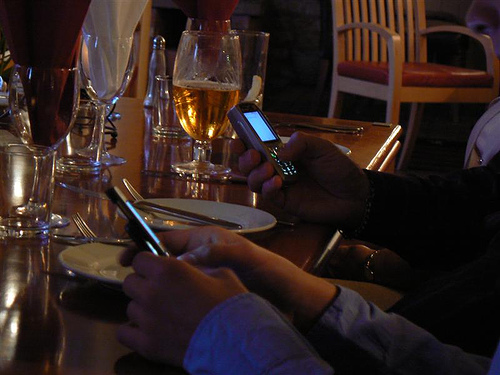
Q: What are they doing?
A: Using phones.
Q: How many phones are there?
A: Two.